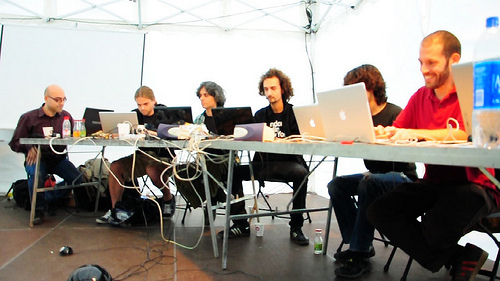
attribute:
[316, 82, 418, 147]
laptop — white, apple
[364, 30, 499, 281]
man — smiling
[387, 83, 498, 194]
shirt — red, collared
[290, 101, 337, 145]
laptop — white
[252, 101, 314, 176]
shirt — black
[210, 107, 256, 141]
laptop — black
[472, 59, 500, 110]
sticker — blue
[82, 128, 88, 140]
sticker — green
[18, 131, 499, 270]
table — steel, white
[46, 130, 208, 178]
wires — white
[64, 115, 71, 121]
cap — red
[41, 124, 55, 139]
cup — white, styrofoam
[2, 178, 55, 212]
bag — black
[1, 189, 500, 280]
floor — tiled, brown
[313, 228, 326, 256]
bottle — empty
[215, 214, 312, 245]
shoes — white, black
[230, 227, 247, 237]
stripes — white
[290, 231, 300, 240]
stripes — white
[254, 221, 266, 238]
cup — white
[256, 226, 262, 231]
design — red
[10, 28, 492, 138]
men — six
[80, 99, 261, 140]
laptops — black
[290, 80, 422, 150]
computers — macs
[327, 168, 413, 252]
jeans — blue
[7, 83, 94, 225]
man — bald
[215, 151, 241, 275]
leg — white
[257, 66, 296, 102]
hair — dark, curly, brown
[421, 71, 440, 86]
smile — bright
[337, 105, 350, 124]
logo — apple